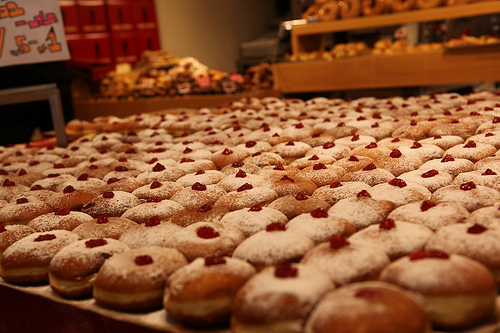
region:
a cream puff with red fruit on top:
[100, 248, 182, 313]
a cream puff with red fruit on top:
[48, 237, 113, 303]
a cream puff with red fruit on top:
[3, 229, 73, 283]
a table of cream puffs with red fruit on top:
[0, 93, 499, 332]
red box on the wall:
[57, 4, 161, 69]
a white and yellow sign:
[0, 1, 67, 63]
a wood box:
[268, 46, 498, 92]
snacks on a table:
[105, 59, 245, 96]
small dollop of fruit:
[197, 223, 221, 238]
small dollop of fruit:
[311, 162, 325, 169]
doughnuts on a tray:
[11, 97, 463, 314]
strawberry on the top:
[121, 249, 163, 271]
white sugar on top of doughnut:
[244, 234, 304, 249]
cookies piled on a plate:
[93, 64, 248, 91]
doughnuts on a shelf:
[289, 0, 483, 17]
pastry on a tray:
[438, 36, 498, 60]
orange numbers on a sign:
[0, 28, 80, 54]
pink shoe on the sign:
[38, 12, 59, 28]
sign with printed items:
[0, 6, 63, 64]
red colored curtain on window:
[63, 7, 155, 43]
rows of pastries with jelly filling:
[3, 85, 494, 330]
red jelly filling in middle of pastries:
[189, 221, 226, 243]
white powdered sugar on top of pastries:
[58, 245, 79, 257]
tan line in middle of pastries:
[159, 291, 231, 318]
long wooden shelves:
[267, 0, 498, 96]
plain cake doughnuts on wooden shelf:
[302, 3, 341, 23]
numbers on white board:
[10, 23, 65, 58]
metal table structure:
[0, 77, 68, 145]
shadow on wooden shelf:
[440, 45, 498, 57]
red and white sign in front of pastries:
[218, 75, 239, 95]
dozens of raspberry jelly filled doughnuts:
[10, 90, 497, 325]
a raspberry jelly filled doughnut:
[161, 250, 247, 323]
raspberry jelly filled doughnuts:
[98, 247, 181, 317]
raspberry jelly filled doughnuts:
[50, 230, 121, 305]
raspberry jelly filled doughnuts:
[5, 233, 69, 294]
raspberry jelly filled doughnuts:
[386, 255, 494, 320]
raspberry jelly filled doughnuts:
[309, 238, 384, 285]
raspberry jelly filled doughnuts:
[237, 220, 310, 264]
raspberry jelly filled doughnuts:
[172, 217, 244, 262]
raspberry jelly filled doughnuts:
[127, 218, 179, 247]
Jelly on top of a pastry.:
[195, 225, 218, 239]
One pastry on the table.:
[91, 245, 187, 312]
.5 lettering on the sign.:
[10, 35, 31, 57]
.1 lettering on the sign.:
[35, 27, 61, 56]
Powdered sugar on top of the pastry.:
[100, 245, 183, 282]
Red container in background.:
[82, 30, 109, 65]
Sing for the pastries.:
[0, 0, 70, 67]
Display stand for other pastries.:
[270, 0, 498, 90]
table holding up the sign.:
[0, 83, 69, 146]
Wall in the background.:
[154, 0, 279, 80]